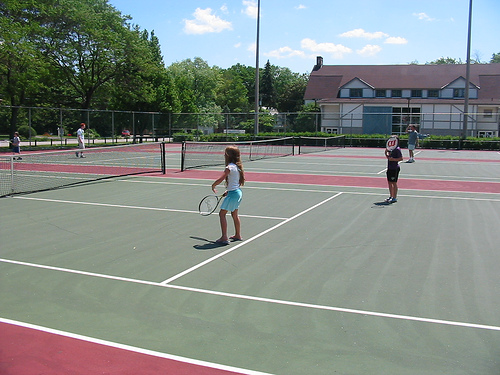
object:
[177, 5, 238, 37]
clouds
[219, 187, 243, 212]
pants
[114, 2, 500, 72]
sky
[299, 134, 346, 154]
tennis net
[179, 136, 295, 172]
tennis net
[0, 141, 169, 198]
tennis net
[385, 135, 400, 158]
racquet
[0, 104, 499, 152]
fence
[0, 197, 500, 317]
ground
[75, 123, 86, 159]
payer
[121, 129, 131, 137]
car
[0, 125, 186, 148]
street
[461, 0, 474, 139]
pole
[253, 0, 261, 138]
pole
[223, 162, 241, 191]
shirt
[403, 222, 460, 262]
turf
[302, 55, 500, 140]
building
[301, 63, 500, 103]
roof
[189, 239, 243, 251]
shadow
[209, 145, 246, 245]
girl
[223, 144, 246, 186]
blonde hair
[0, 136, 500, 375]
court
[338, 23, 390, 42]
clouds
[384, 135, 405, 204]
girl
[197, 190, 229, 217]
racket